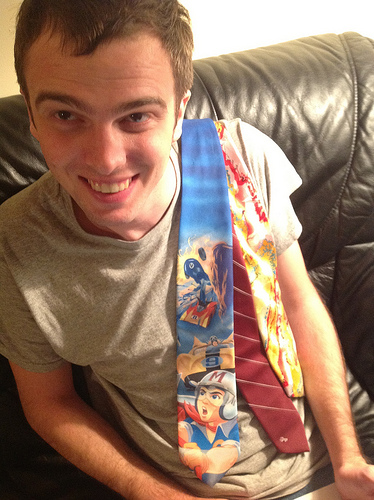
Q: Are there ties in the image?
A: Yes, there is a tie.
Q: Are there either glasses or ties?
A: Yes, there is a tie.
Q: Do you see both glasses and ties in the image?
A: No, there is a tie but no glasses.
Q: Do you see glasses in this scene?
A: No, there are no glasses.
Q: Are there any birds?
A: Yes, there is a bird.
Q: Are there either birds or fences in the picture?
A: Yes, there is a bird.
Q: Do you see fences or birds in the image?
A: Yes, there is a bird.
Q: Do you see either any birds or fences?
A: Yes, there is a bird.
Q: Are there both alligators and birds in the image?
A: No, there is a bird but no alligators.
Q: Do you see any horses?
A: No, there are no horses.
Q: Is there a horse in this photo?
A: No, there are no horses.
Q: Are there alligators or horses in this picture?
A: No, there are no horses or alligators.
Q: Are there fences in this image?
A: No, there are no fences.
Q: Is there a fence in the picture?
A: No, there are no fences.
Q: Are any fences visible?
A: No, there are no fences.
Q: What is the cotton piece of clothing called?
A: The clothing item is a shirt.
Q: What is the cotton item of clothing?
A: The clothing item is a shirt.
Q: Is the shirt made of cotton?
A: Yes, the shirt is made of cotton.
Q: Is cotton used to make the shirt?
A: Yes, the shirt is made of cotton.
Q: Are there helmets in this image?
A: Yes, there is a helmet.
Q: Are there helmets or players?
A: Yes, there is a helmet.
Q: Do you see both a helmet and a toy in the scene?
A: No, there is a helmet but no toys.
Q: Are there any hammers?
A: No, there are no hammers.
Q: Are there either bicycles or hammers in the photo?
A: No, there are no hammers or bicycles.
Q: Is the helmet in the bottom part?
A: Yes, the helmet is in the bottom of the image.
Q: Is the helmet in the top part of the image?
A: No, the helmet is in the bottom of the image.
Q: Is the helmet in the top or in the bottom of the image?
A: The helmet is in the bottom of the image.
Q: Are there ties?
A: Yes, there is a tie.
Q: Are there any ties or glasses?
A: Yes, there is a tie.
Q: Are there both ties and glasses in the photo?
A: No, there is a tie but no glasses.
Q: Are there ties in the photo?
A: Yes, there is a tie.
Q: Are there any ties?
A: Yes, there is a tie.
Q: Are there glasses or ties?
A: Yes, there is a tie.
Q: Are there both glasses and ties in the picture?
A: No, there is a tie but no glasses.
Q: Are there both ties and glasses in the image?
A: No, there is a tie but no glasses.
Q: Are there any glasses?
A: No, there are no glasses.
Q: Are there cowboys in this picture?
A: No, there are no cowboys.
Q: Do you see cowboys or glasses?
A: No, there are no cowboys or glasses.